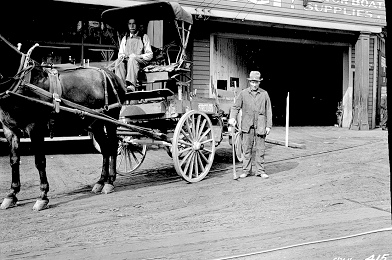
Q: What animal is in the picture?
A: Horse.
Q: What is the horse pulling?
A: Buggy.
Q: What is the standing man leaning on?
A: A cane.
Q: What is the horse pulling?
A: A wagon.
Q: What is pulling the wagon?
A: A horse.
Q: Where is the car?
A: No car.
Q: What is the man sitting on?
A: A bench.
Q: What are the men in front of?
A: A store.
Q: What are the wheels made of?
A: Wood.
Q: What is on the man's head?
A: A hat.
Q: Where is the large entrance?
A: On the right.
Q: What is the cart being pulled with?
A: A horse.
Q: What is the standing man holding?
A: A cane.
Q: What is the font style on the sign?
A: Western.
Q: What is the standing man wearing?
A: A hat.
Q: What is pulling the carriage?
A: A horse.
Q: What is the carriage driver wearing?
A: Overalls.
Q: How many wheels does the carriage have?
A: Two.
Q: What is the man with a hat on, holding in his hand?
A: A pickaxe.